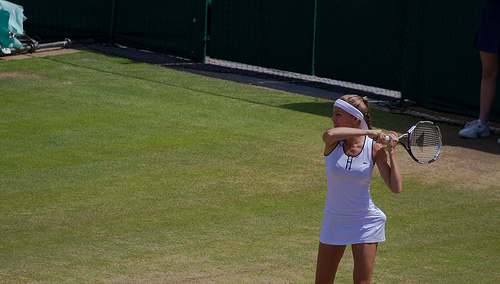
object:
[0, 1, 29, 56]
tarp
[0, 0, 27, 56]
corner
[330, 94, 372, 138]
head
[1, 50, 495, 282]
turf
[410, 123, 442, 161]
wire frame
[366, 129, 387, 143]
hands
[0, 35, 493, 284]
foreground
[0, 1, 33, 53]
plastic covering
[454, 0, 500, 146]
person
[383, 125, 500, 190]
dirt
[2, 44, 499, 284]
court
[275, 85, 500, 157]
shadows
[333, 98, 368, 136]
headband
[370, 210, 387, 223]
tennis ball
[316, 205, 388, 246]
shorts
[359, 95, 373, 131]
braid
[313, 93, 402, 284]
girl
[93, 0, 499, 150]
wall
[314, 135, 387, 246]
dress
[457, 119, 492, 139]
shoe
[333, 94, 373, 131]
hair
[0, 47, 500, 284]
grass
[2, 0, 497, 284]
tennis court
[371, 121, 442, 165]
racket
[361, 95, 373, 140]
pony tail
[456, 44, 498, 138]
leg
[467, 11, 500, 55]
shorts